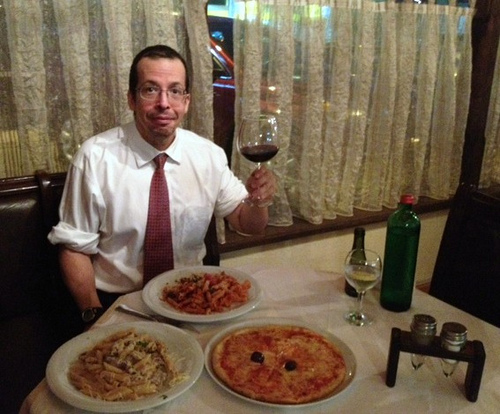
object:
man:
[49, 43, 273, 327]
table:
[21, 261, 499, 413]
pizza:
[210, 322, 348, 404]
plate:
[205, 319, 356, 411]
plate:
[140, 265, 264, 323]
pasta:
[166, 275, 245, 311]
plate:
[43, 319, 206, 411]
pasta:
[65, 332, 187, 401]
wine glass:
[344, 250, 383, 325]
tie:
[142, 152, 175, 285]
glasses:
[132, 82, 185, 101]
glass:
[234, 115, 280, 206]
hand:
[246, 164, 274, 208]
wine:
[241, 144, 279, 162]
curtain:
[0, 1, 475, 238]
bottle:
[378, 192, 421, 311]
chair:
[430, 187, 500, 328]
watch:
[79, 305, 103, 326]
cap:
[400, 192, 414, 203]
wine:
[344, 265, 381, 293]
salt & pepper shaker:
[438, 321, 467, 379]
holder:
[386, 326, 486, 401]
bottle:
[343, 229, 367, 297]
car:
[203, 16, 305, 161]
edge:
[232, 1, 478, 17]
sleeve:
[47, 167, 106, 253]